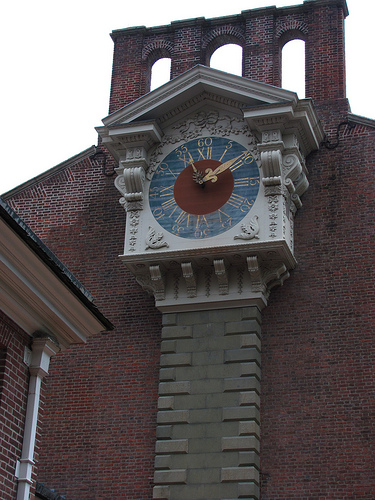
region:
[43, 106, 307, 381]
the clock is blue and red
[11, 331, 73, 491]
the gutter is white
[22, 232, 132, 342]
the trim is black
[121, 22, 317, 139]
there are three brick arches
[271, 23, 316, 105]
arch on top of brick building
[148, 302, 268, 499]
grey bricks under large clock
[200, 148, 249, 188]
gold minute hand on clock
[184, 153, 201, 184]
gold hour hand on clock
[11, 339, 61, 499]
white gutter running down building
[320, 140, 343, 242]
dirty stain running down building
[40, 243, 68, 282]
black shingles on roof of building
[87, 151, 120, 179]
black electrical cord going to clock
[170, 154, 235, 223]
red circle on large clock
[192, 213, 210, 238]
gold roman numbers on clock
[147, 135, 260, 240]
a blue red and gold clock face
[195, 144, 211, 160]
gold roman numeral 12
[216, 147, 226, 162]
gold roman numeral 1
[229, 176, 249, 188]
gold roman numeral 3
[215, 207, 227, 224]
gold roman numeral 5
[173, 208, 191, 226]
gold roman numeral 7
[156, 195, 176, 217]
gold roman numeral 8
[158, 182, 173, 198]
gold roman numeral 9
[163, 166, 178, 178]
gold roman numeral 10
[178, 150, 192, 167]
gold roman numeral 11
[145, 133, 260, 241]
blue clock face with gold letters and hands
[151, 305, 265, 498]
gray brick column below clock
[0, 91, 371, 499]
building made of small red bricks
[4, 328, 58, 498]
downspout of a rain gutter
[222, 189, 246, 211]
roman numeral iii in gold colored metal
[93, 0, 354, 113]
ornate arched crown above clock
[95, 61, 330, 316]
light gray carved clock on building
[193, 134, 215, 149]
number 60 above roman numeral xii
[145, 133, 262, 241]
at the tone the time will be 11:09 am beep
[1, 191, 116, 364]
metal rain gutter below edge of black roofing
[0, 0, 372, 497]
this is a tower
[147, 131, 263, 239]
this is a clock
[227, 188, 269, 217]
a number on the clock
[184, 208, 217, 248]
a number on the clock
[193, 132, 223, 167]
a number on the clock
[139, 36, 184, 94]
this is a watch window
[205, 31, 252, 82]
this is a watch window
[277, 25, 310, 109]
this is a watch window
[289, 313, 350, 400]
the building is bricked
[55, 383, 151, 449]
the building is made of bricks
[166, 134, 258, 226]
60 on the clock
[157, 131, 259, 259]
20 on the clock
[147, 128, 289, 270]
a clock on the building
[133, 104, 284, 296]
an outside clock on the building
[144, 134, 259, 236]
the clock face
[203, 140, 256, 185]
the minute hand of the clock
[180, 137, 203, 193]
the hour hand of the clock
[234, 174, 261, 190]
the 3 o'clock position of theclock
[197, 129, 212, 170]
the 12 o'clock position of theclock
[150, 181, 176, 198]
the 9 o'clock position of theclock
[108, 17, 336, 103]
the red stones above the clock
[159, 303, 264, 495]
the grey stones below the clock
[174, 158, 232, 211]
the red part of the clock face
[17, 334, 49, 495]
a white water drainage pipe on the wall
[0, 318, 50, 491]
a brick wall with white mortar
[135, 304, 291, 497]
a grey brick structure on a red brick wall